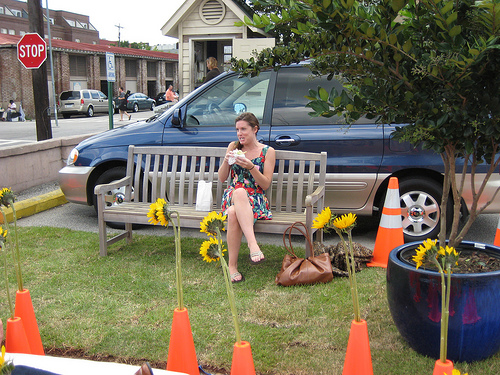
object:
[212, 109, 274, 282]
woman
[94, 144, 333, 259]
bench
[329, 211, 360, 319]
sunflowers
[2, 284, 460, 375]
row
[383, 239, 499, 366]
flower pot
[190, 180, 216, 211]
bag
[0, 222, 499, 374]
lawn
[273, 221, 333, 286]
bag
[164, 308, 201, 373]
traffic cone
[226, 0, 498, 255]
tree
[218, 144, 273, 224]
sundress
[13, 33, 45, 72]
stop sign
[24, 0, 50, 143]
wooden pole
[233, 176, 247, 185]
flowers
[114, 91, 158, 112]
car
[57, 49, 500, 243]
van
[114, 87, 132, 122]
people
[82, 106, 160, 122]
sidewalk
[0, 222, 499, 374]
grass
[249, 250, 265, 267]
slippers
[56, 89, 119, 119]
cars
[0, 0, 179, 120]
building